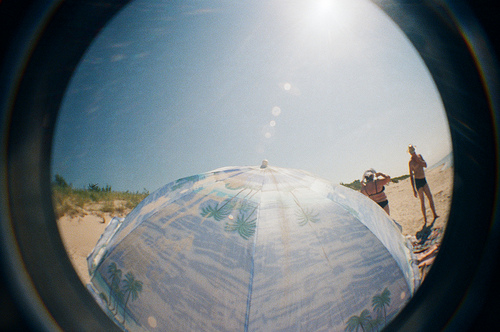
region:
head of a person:
[403, 138, 418, 155]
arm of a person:
[402, 170, 423, 196]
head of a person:
[360, 164, 379, 185]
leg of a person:
[415, 194, 427, 218]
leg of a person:
[426, 187, 438, 207]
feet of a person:
[426, 208, 451, 221]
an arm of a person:
[357, 171, 371, 186]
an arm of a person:
[370, 167, 392, 179]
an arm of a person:
[403, 168, 417, 190]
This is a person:
[354, 156, 404, 236]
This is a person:
[389, 131, 459, 253]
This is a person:
[396, 135, 455, 232]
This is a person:
[350, 158, 420, 255]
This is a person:
[401, 141, 443, 253]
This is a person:
[349, 157, 397, 242]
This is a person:
[356, 150, 398, 253]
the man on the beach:
[407, 144, 438, 221]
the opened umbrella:
[87, 160, 419, 328]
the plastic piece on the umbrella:
[260, 158, 268, 168]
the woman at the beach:
[359, 170, 391, 214]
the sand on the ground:
[54, 161, 454, 288]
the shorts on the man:
[413, 177, 427, 188]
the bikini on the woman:
[361, 180, 389, 208]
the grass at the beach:
[49, 170, 412, 201]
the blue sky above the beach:
[50, 0, 452, 193]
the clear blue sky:
[111, 15, 189, 117]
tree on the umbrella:
[227, 204, 263, 244]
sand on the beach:
[66, 217, 98, 241]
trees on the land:
[50, 170, 101, 192]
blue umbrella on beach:
[99, 161, 409, 329]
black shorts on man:
[409, 170, 429, 188]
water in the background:
[428, 155, 458, 168]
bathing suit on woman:
[362, 183, 388, 207]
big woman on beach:
[352, 168, 398, 208]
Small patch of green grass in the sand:
[57, 190, 85, 217]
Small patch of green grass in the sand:
[75, 188, 95, 219]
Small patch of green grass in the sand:
[81, 189, 118, 213]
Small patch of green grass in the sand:
[97, 173, 126, 199]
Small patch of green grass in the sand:
[345, 172, 360, 193]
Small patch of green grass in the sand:
[387, 168, 409, 188]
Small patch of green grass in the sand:
[52, 191, 106, 224]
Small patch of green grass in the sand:
[85, 176, 122, 206]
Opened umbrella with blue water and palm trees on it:
[85, 157, 423, 330]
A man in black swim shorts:
[404, 144, 438, 224]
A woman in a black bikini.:
[357, 170, 389, 214]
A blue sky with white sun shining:
[50, 4, 451, 188]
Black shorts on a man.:
[412, 175, 426, 190]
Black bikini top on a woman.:
[361, 177, 385, 196]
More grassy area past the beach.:
[50, 173, 150, 223]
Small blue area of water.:
[433, 152, 453, 169]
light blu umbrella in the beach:
[82, 167, 424, 329]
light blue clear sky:
[52, 4, 456, 192]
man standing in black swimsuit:
[403, 140, 438, 222]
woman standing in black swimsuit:
[361, 168, 392, 215]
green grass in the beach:
[50, 176, 155, 206]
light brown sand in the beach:
[52, 164, 453, 280]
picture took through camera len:
[2, 5, 492, 326]